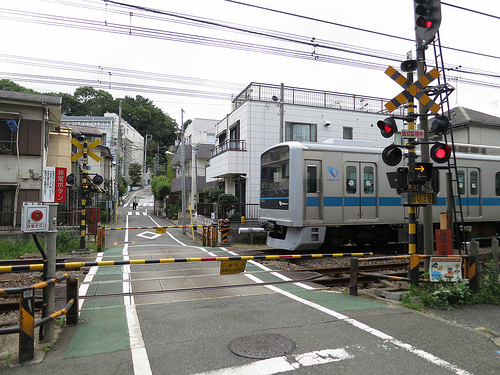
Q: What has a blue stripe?
A: Train.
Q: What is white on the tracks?
A: Train.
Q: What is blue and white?
A: Train.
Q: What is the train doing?
A: Moving.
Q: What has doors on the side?
A: Train.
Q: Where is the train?
A: Behind red lights.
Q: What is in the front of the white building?
A: Train.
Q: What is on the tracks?
A: Train.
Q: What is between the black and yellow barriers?
A: Train.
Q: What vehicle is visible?
A: Train.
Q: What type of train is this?
A: Passenger.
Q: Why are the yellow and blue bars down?
A: A train is crossing.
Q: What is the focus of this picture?
A: Railroad crossing.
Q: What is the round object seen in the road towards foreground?
A: Manhole cover.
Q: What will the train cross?
A: The road.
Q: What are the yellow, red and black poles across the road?
A: Guard rails.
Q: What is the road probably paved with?
A: Asphalt.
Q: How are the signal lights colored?
A: Red.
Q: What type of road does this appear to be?
A: One-way.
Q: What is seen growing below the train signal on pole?
A: Plants.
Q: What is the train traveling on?
A: Railroad tracks.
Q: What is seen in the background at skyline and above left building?
A: Trees.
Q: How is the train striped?
A: Horizontally.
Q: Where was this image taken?
A: On a street, in front of a train.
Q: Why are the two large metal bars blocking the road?
A: A train is passing.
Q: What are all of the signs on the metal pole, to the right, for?
A: To warn people about oncoming trains.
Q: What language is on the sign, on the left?
A: Japanese.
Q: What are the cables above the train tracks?
A: They are power lines.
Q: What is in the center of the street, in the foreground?
A: A manhole.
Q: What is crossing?
A: A train.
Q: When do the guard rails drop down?
A: Oncoming trains.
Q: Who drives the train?
A: The engineer.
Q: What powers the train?
A: Electricity.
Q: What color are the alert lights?
A: Red.